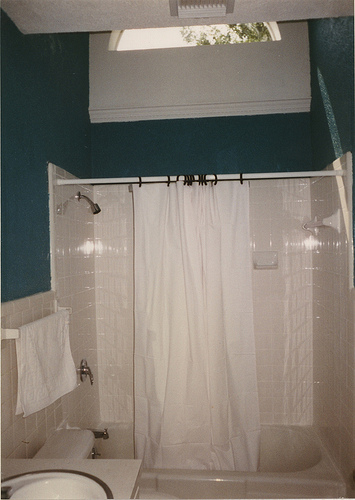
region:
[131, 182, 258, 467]
The curtain is white.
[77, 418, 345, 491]
The tub is white.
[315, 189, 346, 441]
The tile is white.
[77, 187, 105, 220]
The showerhead is chrome.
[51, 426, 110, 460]
The toilet is white.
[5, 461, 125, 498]
The sink has silver trim.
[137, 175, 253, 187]
There are 12 curtain rings.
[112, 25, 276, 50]
The window is closed.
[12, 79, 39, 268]
The wall is blue.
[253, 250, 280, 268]
The soap holder is white.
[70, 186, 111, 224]
this is a shower head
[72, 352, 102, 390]
a knob to turn on the water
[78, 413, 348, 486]
this is a bathtub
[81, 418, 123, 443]
this is a water faucet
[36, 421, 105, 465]
the tank lid of a toilet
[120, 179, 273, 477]
this is a shower curtain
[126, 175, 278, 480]
the shower curtain is white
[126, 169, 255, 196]
black shower curtain rings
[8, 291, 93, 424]
a white towel on a rack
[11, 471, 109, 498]
this is the sink bowl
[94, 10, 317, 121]
white wall near window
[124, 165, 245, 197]
black hooks on shower rod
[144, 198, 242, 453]
white shower curtain on rod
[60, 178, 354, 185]
shower rod is white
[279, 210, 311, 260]
white tile shower wall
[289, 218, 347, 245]
white bar in shower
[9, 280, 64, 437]
white towel on rod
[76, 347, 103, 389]
chrome handle on shower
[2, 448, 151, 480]
tan counter with sink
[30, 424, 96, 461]
white toilet tank near shower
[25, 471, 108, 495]
Wide shallow table sink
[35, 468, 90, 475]
Silver plated table sink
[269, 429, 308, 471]
Clean wide bath tub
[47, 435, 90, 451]
Toilet bowl on wall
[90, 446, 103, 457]
Silver toilet bowl flash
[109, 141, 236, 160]
Green colored shower roof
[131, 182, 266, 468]
The curtain is white.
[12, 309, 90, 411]
The towel is white.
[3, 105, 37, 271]
The wall is blue.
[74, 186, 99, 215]
The shower head is silver.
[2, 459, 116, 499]
The sink has silver trim.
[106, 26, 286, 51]
The window is closed.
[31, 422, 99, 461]
The toilet is white.